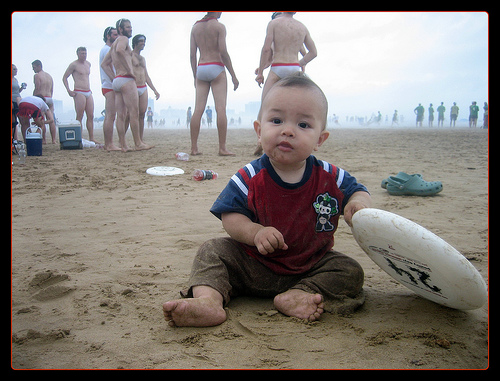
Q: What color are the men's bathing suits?
A: White.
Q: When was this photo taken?
A: Day time.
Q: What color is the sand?
A: Brown.